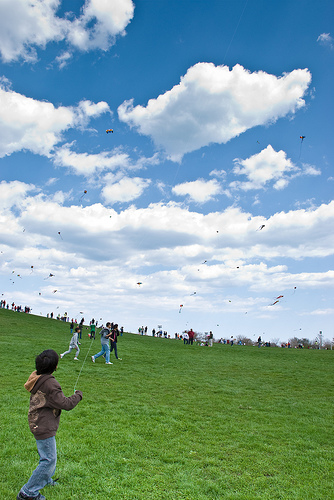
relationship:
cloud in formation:
[1, 1, 130, 62] [0, 0, 333, 339]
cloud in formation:
[3, 86, 109, 158] [0, 0, 333, 339]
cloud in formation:
[115, 61, 308, 156] [0, 0, 333, 339]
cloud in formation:
[22, 199, 327, 262] [0, 0, 333, 339]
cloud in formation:
[238, 143, 299, 187] [0, 0, 333, 339]